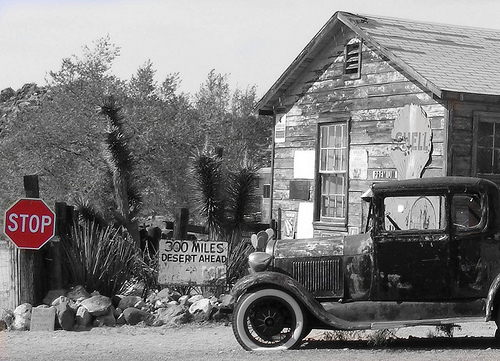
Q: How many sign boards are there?
A: 1.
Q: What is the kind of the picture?
A: Black and white.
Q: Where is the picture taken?
A: In the desert.